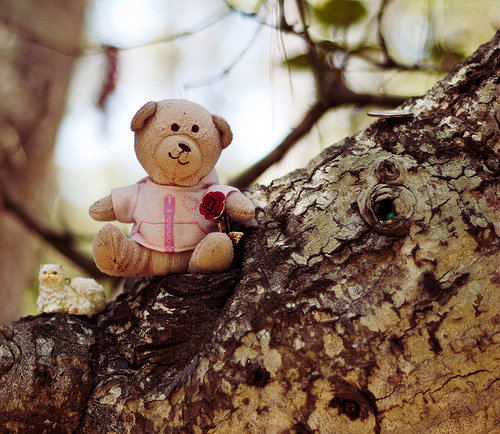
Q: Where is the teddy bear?
A: In the tree.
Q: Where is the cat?
A: Next to the teddy bear.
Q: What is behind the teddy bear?
A: Tree branches.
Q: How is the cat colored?
A: The cat is white.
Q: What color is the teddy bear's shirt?
A: The shirt is pink.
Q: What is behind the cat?
A: Tree branches are behind the cat.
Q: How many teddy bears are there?
A: One teddy bear.